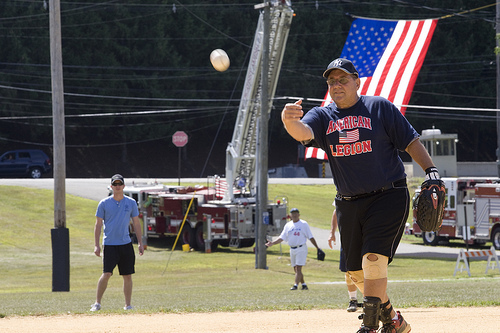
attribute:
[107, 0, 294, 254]
firetruck — white, red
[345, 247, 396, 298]
knee pads — brown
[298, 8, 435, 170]
flag — american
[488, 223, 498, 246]
wheel — rear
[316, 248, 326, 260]
baseball glove — black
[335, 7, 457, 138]
flag — american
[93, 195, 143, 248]
shirt — blue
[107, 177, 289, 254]
firetruck — red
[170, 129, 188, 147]
stop sign — red, white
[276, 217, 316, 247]
t-shirt — white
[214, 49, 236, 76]
baseball — white